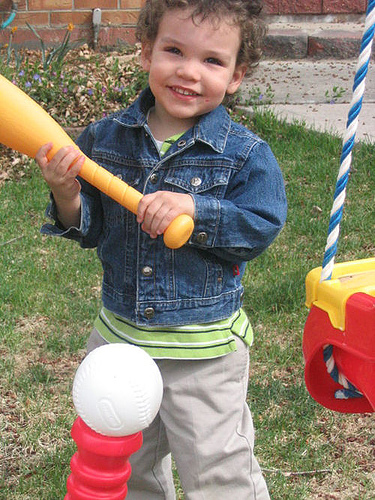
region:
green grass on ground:
[9, 286, 25, 304]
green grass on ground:
[9, 258, 44, 284]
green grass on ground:
[44, 272, 70, 317]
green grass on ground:
[48, 269, 67, 281]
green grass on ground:
[70, 257, 91, 281]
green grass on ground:
[253, 282, 275, 301]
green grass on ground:
[277, 267, 290, 284]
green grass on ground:
[295, 238, 311, 259]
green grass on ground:
[273, 328, 294, 362]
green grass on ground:
[258, 340, 282, 372]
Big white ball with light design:
[69, 341, 167, 441]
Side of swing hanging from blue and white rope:
[303, 1, 373, 414]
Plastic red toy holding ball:
[56, 340, 163, 498]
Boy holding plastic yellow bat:
[1, 0, 285, 337]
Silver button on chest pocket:
[185, 173, 207, 191]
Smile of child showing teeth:
[165, 82, 203, 103]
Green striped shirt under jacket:
[93, 307, 254, 356]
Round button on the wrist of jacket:
[195, 228, 213, 243]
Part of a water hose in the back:
[0, 0, 26, 32]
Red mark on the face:
[202, 94, 216, 106]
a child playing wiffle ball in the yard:
[14, 8, 279, 270]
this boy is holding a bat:
[9, 22, 309, 282]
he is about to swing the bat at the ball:
[9, 7, 322, 272]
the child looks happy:
[107, 4, 276, 156]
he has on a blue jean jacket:
[51, 113, 256, 328]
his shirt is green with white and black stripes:
[78, 303, 260, 356]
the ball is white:
[48, 330, 177, 431]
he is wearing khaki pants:
[168, 360, 275, 498]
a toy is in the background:
[292, 110, 374, 378]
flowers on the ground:
[29, 27, 133, 106]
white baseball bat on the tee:
[57, 332, 172, 435]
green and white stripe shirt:
[173, 330, 221, 352]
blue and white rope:
[320, 346, 339, 389]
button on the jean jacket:
[140, 263, 155, 281]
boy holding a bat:
[21, 0, 292, 333]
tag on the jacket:
[230, 262, 240, 278]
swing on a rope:
[289, 258, 373, 423]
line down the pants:
[231, 414, 252, 461]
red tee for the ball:
[66, 428, 133, 498]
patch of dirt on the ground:
[12, 393, 26, 469]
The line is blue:
[354, 24, 373, 47]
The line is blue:
[350, 65, 369, 83]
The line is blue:
[339, 99, 365, 123]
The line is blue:
[332, 131, 358, 159]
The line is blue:
[328, 166, 352, 193]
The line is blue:
[321, 209, 347, 230]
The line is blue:
[320, 237, 339, 264]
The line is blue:
[320, 340, 332, 361]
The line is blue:
[328, 360, 340, 386]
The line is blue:
[339, 384, 360, 403]